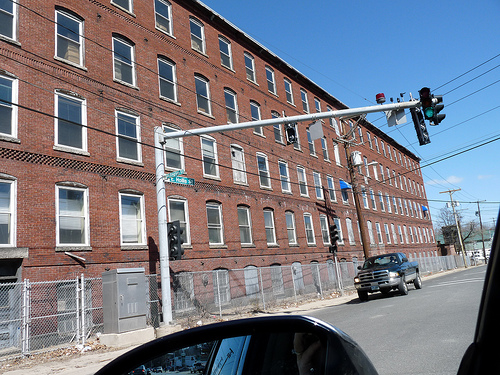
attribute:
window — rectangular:
[53, 10, 83, 65]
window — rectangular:
[110, 35, 132, 84]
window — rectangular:
[156, 56, 177, 101]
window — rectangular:
[193, 69, 210, 116]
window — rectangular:
[224, 89, 239, 124]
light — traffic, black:
[394, 83, 465, 131]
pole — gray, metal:
[138, 97, 336, 165]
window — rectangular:
[48, 173, 106, 258]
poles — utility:
[150, 84, 441, 325]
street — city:
[318, 250, 487, 374]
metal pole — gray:
[141, 114, 178, 338]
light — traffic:
[412, 70, 452, 130]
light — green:
[373, 54, 466, 154]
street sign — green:
[163, 172, 193, 189]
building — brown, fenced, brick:
[0, 1, 440, 356]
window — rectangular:
[108, 102, 150, 168]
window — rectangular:
[230, 140, 253, 190]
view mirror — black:
[137, 313, 358, 373]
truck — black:
[351, 250, 430, 305]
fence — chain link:
[1, 241, 476, 358]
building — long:
[0, 12, 421, 311]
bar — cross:
[154, 100, 419, 137]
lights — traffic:
[404, 104, 438, 146]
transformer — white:
[345, 136, 379, 184]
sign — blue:
[165, 177, 192, 184]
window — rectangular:
[115, 113, 142, 164]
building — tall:
[165, 33, 403, 221]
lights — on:
[424, 104, 434, 128]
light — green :
[417, 88, 438, 124]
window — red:
[218, 106, 442, 216]